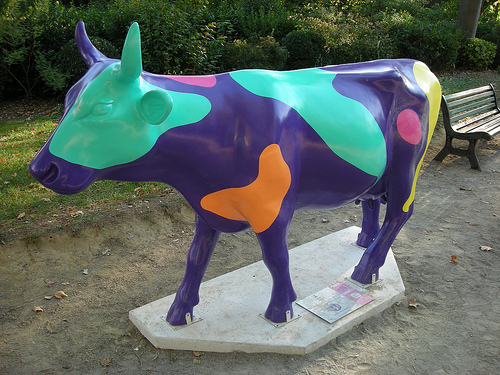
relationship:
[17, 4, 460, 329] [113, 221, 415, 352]
cow on base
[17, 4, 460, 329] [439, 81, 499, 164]
cow next to bench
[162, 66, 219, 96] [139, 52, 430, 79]
circle on back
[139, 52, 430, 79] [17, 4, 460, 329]
back on cow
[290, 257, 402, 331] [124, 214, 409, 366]
plaque on statue base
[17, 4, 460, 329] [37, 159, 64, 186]
cow has nostril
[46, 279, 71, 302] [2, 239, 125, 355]
leaf on ground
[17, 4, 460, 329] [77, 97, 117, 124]
cow has eye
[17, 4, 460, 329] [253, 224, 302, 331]
cow has leg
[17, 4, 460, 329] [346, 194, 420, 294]
cow has leg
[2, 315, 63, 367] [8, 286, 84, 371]
imprints on dirt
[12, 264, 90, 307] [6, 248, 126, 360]
imprints in dirt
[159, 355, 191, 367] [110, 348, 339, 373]
imprints in dirt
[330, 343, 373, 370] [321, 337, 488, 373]
imprints on dirt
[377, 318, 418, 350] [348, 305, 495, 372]
imprints on dirt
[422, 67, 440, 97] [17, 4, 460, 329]
yellow on cow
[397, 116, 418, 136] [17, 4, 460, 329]
pink on cow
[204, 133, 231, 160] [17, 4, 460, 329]
purple on cow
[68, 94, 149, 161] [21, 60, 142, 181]
green on face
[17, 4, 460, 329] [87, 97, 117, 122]
cow has eye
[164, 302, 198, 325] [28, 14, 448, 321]
left foot on cow